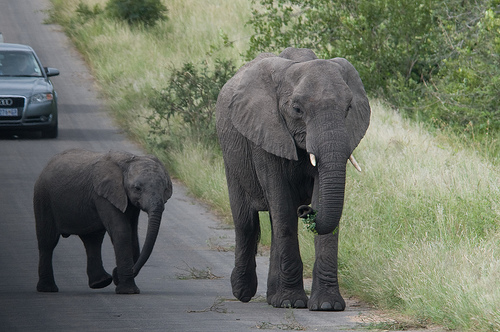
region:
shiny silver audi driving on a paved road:
[0, 35, 72, 148]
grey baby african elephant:
[25, 140, 179, 304]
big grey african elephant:
[207, 38, 373, 314]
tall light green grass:
[49, 0, 498, 327]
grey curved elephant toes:
[305, 295, 348, 312]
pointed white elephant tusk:
[300, 146, 320, 168]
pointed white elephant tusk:
[342, 148, 362, 177]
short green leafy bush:
[97, 2, 172, 34]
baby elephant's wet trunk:
[105, 200, 170, 282]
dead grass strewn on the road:
[171, 223, 404, 329]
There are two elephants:
[23, 37, 372, 329]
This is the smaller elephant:
[21, 133, 178, 304]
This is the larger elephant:
[211, 58, 384, 298]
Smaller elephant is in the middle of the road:
[27, 133, 171, 307]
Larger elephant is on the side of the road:
[212, 40, 385, 322]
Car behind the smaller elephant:
[0, 35, 72, 150]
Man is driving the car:
[10, 46, 44, 80]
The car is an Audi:
[0, 34, 63, 143]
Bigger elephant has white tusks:
[295, 138, 372, 174]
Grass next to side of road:
[127, 3, 494, 329]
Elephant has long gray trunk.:
[130, 211, 199, 328]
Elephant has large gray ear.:
[86, 153, 132, 214]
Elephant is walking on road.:
[21, 226, 166, 295]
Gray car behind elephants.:
[13, 58, 59, 133]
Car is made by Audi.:
[0, 85, 14, 122]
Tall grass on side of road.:
[383, 164, 465, 297]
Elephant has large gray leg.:
[228, 188, 253, 310]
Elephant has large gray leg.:
[276, 210, 311, 319]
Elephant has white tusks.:
[299, 138, 380, 183]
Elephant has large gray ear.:
[232, 60, 294, 157]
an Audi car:
[2, 32, 82, 136]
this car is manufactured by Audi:
[0, 31, 82, 141]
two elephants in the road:
[25, 29, 414, 326]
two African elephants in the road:
[12, 44, 406, 316]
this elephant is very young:
[23, 123, 184, 310]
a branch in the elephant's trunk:
[281, 184, 386, 269]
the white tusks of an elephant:
[288, 137, 385, 181]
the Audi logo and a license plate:
[0, 89, 33, 118]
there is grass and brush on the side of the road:
[85, 3, 498, 290]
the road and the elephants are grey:
[4, 6, 402, 331]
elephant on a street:
[187, 33, 377, 315]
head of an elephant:
[221, 52, 394, 189]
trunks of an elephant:
[292, 143, 373, 173]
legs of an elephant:
[217, 202, 382, 314]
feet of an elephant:
[288, 276, 356, 316]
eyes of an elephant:
[283, 75, 360, 124]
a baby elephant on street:
[10, 150, 195, 292]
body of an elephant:
[182, 21, 314, 154]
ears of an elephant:
[210, 45, 302, 171]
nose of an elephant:
[301, 163, 361, 233]